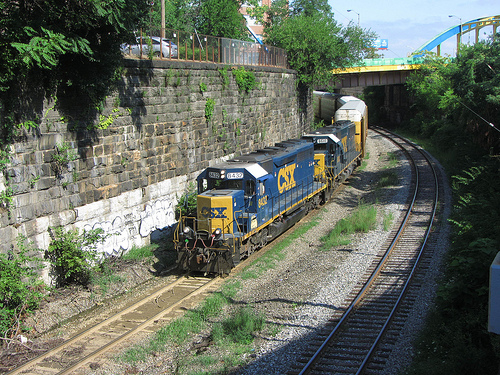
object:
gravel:
[302, 271, 329, 299]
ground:
[0, 125, 500, 375]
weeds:
[319, 198, 395, 252]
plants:
[216, 64, 263, 92]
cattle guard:
[176, 226, 237, 276]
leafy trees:
[403, 32, 499, 111]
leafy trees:
[245, 0, 384, 97]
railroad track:
[334, 124, 445, 316]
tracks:
[7, 275, 220, 375]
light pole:
[456, 33, 460, 54]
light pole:
[347, 10, 360, 27]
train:
[172, 89, 369, 279]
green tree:
[2, 0, 155, 129]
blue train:
[193, 135, 362, 229]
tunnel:
[378, 83, 415, 123]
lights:
[216, 230, 220, 235]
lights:
[184, 227, 189, 233]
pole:
[161, 0, 166, 37]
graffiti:
[0, 169, 203, 286]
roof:
[335, 96, 367, 122]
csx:
[278, 163, 297, 193]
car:
[120, 36, 178, 57]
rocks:
[104, 68, 271, 262]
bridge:
[314, 16, 500, 91]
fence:
[129, 24, 290, 69]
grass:
[209, 296, 284, 346]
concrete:
[314, 70, 412, 90]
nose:
[198, 194, 234, 233]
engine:
[175, 151, 364, 274]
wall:
[0, 59, 421, 298]